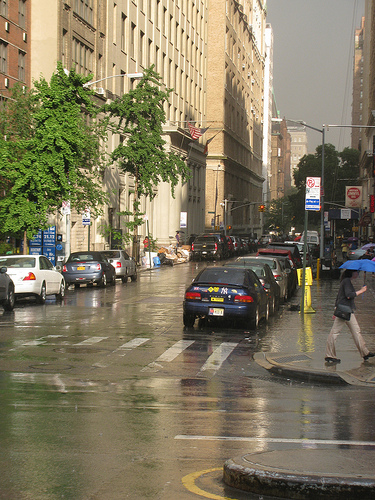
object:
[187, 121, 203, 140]
american flag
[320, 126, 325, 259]
pole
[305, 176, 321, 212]
sign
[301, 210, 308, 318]
pole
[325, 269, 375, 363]
person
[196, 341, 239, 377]
line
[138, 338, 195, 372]
line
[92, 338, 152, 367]
line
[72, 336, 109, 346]
line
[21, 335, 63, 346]
line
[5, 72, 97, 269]
green trees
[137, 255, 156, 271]
sidewalk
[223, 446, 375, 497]
median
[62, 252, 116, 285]
car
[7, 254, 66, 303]
vehicle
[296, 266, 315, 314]
sign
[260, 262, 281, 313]
car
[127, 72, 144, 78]
street light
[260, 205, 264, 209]
street light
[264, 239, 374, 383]
sidewalk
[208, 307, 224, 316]
license plate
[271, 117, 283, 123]
street light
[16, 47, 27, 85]
window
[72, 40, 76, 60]
window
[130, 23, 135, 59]
window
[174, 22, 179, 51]
window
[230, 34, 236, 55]
window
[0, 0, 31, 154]
building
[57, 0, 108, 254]
building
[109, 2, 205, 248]
building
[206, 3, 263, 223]
building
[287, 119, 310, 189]
building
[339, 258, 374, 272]
umbrella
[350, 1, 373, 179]
buildings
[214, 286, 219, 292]
stickers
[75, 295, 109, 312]
rain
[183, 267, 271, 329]
car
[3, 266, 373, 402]
street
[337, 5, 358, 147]
wires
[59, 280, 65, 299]
wheel